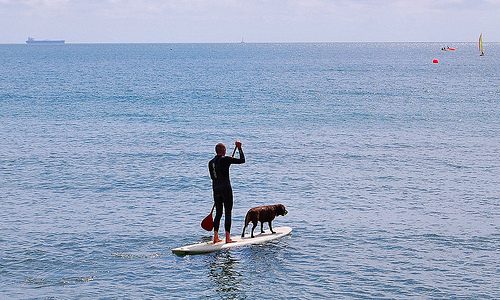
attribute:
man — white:
[197, 141, 248, 238]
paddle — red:
[201, 144, 242, 230]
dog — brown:
[246, 196, 286, 238]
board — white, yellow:
[168, 219, 296, 261]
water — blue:
[7, 47, 496, 299]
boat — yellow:
[468, 42, 491, 63]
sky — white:
[0, 2, 500, 47]